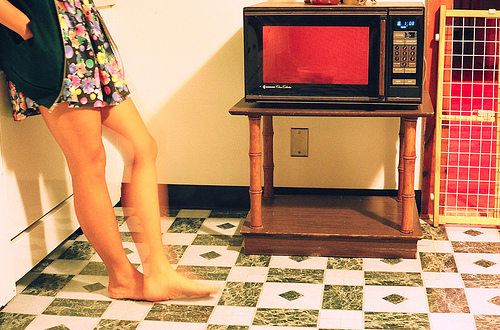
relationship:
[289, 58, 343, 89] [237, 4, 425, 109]
dish in microwave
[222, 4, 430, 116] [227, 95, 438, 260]
microwave on stand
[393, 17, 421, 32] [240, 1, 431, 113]
display on microwave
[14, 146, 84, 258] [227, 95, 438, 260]
shadow on stand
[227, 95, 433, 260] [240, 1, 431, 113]
stand under microwave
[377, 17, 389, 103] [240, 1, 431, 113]
handle on microwave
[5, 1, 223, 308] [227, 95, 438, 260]
woman leaning on stand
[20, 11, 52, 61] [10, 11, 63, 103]
hand in pocket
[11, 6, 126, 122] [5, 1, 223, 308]
floral skirt on woman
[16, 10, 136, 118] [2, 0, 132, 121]
floral pattern on dress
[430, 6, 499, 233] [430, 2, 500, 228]
baby gate in baby gate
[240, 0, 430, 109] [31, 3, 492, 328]
microwave in kitchen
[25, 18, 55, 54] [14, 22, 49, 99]
hand in pocket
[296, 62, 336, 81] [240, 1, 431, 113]
food inside microwave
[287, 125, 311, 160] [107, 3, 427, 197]
socket on wall